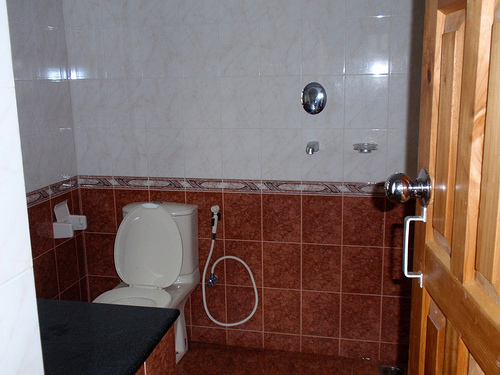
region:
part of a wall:
[188, 37, 251, 109]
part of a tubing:
[234, 271, 278, 332]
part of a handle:
[390, 230, 415, 294]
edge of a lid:
[171, 197, 189, 283]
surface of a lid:
[116, 237, 164, 284]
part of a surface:
[71, 326, 118, 361]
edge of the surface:
[147, 328, 169, 352]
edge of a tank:
[181, 218, 200, 262]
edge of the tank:
[166, 207, 194, 222]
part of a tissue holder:
[66, 209, 93, 249]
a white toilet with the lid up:
[112, 205, 189, 301]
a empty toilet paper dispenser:
[54, 209, 93, 239]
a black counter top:
[47, 307, 146, 357]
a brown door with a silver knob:
[389, 13, 499, 360]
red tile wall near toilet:
[262, 207, 379, 332]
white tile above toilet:
[77, 13, 260, 152]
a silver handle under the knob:
[402, 212, 427, 294]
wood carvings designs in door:
[430, 13, 470, 174]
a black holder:
[209, 215, 226, 227]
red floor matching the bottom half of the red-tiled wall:
[187, 356, 285, 370]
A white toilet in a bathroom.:
[91, 200, 201, 365]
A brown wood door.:
[403, 0, 495, 370]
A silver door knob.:
[381, 166, 429, 204]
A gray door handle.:
[400, 205, 426, 286]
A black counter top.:
[35, 295, 181, 373]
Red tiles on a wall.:
[26, 185, 406, 365]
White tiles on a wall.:
[5, 0, 425, 195]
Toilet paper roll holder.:
[50, 196, 86, 237]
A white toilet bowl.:
[90, 285, 171, 306]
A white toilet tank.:
[120, 200, 200, 283]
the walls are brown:
[248, 208, 388, 338]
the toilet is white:
[105, 211, 213, 305]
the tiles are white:
[183, 132, 297, 169]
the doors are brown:
[441, 140, 493, 323]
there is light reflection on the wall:
[340, 54, 407, 117]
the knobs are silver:
[379, 171, 440, 290]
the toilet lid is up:
[103, 200, 215, 300]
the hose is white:
[190, 215, 276, 326]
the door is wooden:
[428, 143, 494, 339]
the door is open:
[399, 82, 494, 217]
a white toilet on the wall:
[93, 176, 211, 353]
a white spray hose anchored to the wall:
[183, 192, 275, 330]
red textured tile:
[241, 195, 392, 345]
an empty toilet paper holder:
[48, 156, 95, 246]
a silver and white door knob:
[373, 166, 439, 290]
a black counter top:
[43, 285, 224, 373]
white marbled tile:
[93, 45, 244, 161]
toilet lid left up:
[93, 180, 188, 349]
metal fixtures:
[273, 130, 395, 167]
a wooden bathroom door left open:
[415, 6, 498, 361]